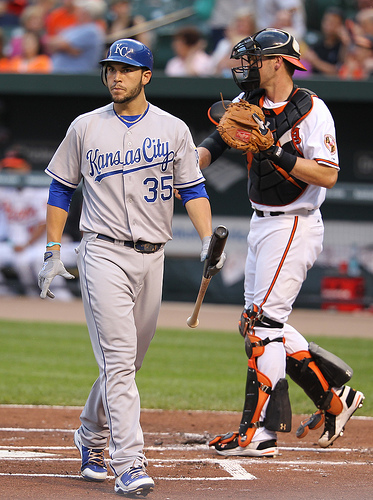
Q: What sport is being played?
A: Baseball.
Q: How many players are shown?
A: Two.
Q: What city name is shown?
A: Kansas city.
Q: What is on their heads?
A: Helmets.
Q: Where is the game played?
A: Field.